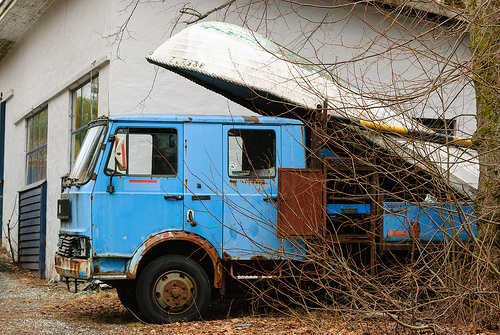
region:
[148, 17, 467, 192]
a boat sitting on top of the truck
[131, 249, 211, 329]
the wheel of the truck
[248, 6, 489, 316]
many dried out tree branches with no leaves on it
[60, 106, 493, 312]
the blue truck sitting on the ground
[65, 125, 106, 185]
the front window of the truck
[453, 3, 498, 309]
the tree next to the truck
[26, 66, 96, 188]
the windows on the building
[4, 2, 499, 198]
the house next to the truck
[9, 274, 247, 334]
the dried out ground below the semi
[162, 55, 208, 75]
the numbers on the boat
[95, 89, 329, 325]
This is a truck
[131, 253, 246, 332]
This is a wheel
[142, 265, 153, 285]
This is a tire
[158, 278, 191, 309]
The wheel is rusted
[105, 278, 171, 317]
The tire is black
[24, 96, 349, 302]
The truck is blue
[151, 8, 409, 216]
This is a white boat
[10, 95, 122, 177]
These are windows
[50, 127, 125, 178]
This is the driver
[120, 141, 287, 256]
The truck is old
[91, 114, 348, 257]
this is a lorry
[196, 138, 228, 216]
the lorry is blue in color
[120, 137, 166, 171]
this is the window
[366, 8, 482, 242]
this is a tree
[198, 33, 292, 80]
this is a boat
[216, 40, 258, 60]
the boat is white in color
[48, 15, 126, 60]
this is a wall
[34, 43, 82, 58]
the wall is white in color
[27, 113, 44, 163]
this is a window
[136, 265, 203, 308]
this is the wheel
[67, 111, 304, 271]
blue cab of truck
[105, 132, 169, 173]
window on driver's side door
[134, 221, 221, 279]
rust on side of blue truck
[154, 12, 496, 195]
white boat on back of blue truck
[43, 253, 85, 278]
front bumper with rust marks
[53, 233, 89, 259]
front grill of blue truck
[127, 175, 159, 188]
red stripe under driver's side window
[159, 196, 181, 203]
door handle of driver's door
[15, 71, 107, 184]
two windows of white building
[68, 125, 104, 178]
front windshield of blue truck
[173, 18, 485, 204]
a white boat upside down on a truck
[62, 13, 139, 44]
white walls of the building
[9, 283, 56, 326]
grey gravel of the driveway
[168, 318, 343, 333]
many fallen leaves on the ground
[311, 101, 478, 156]
a black and yellow pole on the truck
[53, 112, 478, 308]
a blue rusted truck in a driveway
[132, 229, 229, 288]
rust around the wheel well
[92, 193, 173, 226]
blue door of the truck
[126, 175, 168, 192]
red stripe on the blue truck door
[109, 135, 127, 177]
white side mirror of the truck